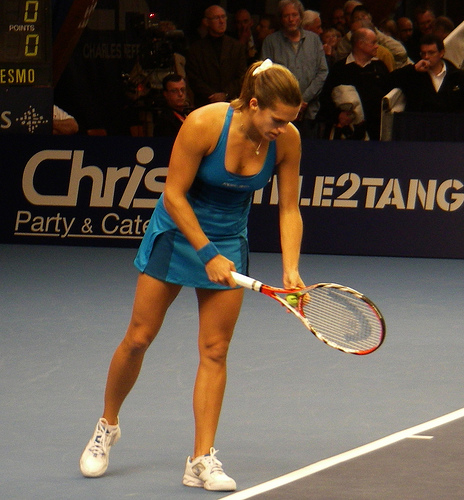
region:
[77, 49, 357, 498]
A woman playing tennis.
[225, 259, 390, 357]
A red and white tennis racket.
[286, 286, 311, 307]
A yellow tennis ball.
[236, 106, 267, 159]
A gold necklace around woman's neck.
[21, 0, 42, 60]
A set of points on a scoreboard.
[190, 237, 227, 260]
A blue wrist band.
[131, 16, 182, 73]
A camera filming tennis game.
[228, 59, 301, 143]
A woman with a ponytail.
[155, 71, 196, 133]
A man sitting in stands.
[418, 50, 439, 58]
Glasses on a mans face.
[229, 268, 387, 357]
tennis racket and ball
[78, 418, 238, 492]
white and grey sneakers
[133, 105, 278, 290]
blue tennis outfit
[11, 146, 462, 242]
white writing on navy blue wall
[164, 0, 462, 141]
people in audience watching tennis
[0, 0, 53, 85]
yellow and black score sign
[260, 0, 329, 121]
man in grey shirt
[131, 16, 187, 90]
cameraman recording tennis match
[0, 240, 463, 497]
grey and blue tennis court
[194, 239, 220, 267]
blue band on wrist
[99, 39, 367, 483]
a woman holding a tennis racket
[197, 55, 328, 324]
a woman holding a tennis ball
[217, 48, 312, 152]
a woman with her hair in a ponytail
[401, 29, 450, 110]
a man with his hand to his mouth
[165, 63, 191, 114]
a man wearing glasses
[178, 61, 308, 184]
a woman wearing a gold necklace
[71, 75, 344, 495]
a woman wearing white tennis shoes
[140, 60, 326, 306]
a woman wearing a blue tennis dress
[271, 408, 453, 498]
white lines painted on tennis court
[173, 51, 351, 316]
a woman wearing a blue wrist band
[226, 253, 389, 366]
tennis racket with tennis ball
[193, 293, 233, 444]
woman's bare shaved leg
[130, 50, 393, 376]
woman playing tennis with racket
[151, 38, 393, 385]
female tennis player preparing to serve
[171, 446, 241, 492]
white tennis shoes with laces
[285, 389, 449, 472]
white lines on a tennis court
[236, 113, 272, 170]
gold locket around a neck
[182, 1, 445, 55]
spectators to a tennis game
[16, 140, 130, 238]
white lettering on a blue background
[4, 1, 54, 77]
scoreboard at a tennis game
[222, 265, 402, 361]
Tennis racket in woman's hand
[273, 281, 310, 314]
Green ball in woman's hand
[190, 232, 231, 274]
Blue wristband on woman's arm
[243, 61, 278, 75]
White headband on woman's hair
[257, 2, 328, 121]
Man wearing a blue shirt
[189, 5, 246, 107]
Man wearing brown blazer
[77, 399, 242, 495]
White tennis shoes on woman's feet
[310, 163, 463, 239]
White letters on blue wall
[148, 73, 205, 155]
Man sitting near wall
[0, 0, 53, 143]
Scoreboard with green numbers